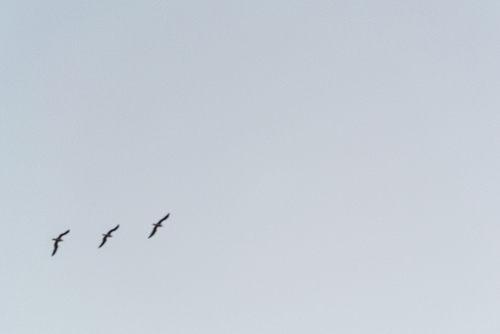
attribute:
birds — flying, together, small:
[48, 210, 172, 255]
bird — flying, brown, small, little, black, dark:
[148, 212, 171, 237]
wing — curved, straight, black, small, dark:
[158, 212, 170, 222]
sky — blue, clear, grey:
[1, 1, 499, 333]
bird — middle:
[97, 222, 120, 247]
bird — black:
[146, 209, 183, 251]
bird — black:
[78, 214, 139, 247]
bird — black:
[39, 222, 83, 269]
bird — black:
[144, 211, 205, 271]